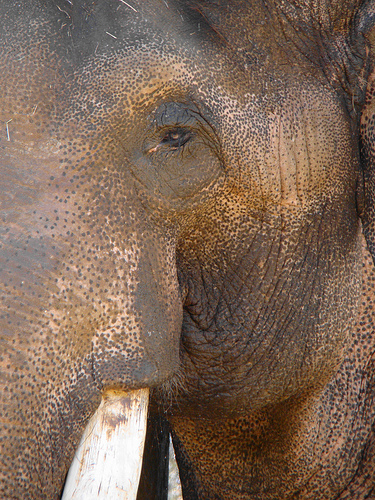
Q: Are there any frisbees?
A: No, there are no frisbees.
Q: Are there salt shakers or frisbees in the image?
A: No, there are no frisbees or salt shakers.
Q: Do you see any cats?
A: No, there are no cats.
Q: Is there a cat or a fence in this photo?
A: No, there are no cats or fences.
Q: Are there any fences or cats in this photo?
A: No, there are no cats or fences.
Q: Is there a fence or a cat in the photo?
A: No, there are no cats or fences.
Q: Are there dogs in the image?
A: No, there are no dogs.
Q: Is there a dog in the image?
A: No, there are no dogs.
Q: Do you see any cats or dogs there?
A: No, there are no dogs or cats.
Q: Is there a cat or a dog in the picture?
A: No, there are no dogs or cats.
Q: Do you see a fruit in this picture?
A: No, there are no fruits.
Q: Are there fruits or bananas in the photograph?
A: No, there are no fruits or bananas.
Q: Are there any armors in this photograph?
A: No, there are no armors.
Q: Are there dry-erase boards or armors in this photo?
A: No, there are no armors or dry-erase boards.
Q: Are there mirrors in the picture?
A: No, there are no mirrors.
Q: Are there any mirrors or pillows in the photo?
A: No, there are no mirrors or pillows.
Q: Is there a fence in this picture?
A: No, there are no fences.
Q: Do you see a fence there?
A: No, there are no fences.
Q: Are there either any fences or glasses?
A: No, there are no fences or glasses.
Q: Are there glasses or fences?
A: No, there are no fences or glasses.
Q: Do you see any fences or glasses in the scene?
A: No, there are no fences or glasses.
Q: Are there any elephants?
A: Yes, there is an elephant.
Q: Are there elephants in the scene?
A: Yes, there is an elephant.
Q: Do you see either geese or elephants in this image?
A: Yes, there is an elephant.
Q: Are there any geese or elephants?
A: Yes, there is an elephant.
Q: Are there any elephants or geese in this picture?
A: Yes, there is an elephant.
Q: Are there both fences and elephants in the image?
A: No, there is an elephant but no fences.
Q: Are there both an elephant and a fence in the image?
A: No, there is an elephant but no fences.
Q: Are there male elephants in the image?
A: Yes, there is a male elephant.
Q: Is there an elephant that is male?
A: Yes, there is an elephant that is male.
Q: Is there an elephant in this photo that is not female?
A: Yes, there is a male elephant.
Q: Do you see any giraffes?
A: No, there are no giraffes.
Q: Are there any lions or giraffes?
A: No, there are no giraffes or lions.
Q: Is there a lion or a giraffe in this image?
A: No, there are no giraffes or lions.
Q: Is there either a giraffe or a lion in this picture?
A: No, there are no giraffes or lions.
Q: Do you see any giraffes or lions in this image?
A: No, there are no giraffes or lions.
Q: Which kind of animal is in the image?
A: The animal is an elephant.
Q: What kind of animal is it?
A: The animal is an elephant.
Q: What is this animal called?
A: That is an elephant.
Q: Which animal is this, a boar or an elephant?
A: That is an elephant.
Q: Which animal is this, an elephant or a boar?
A: That is an elephant.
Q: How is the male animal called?
A: The animal is an elephant.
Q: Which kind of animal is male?
A: The animal is an elephant.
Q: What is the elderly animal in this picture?
A: The animal is an elephant.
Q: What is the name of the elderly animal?
A: The animal is an elephant.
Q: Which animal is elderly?
A: The animal is an elephant.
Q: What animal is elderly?
A: The animal is an elephant.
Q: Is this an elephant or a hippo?
A: This is an elephant.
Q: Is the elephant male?
A: Yes, the elephant is male.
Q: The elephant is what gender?
A: The elephant is male.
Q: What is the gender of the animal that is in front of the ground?
A: The elephant is male.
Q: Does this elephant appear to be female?
A: No, the elephant is male.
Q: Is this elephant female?
A: No, the elephant is male.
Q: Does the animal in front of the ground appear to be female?
A: No, the elephant is male.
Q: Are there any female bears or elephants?
A: No, there is an elephant but he is male.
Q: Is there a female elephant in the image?
A: No, there is an elephant but he is male.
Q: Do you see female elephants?
A: No, there is an elephant but he is male.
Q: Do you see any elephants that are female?
A: No, there is an elephant but he is male.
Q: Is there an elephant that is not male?
A: No, there is an elephant but he is male.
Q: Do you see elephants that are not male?
A: No, there is an elephant but he is male.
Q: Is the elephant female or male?
A: The elephant is male.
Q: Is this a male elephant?
A: Yes, this is a male elephant.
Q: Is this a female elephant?
A: No, this is a male elephant.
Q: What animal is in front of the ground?
A: The elephant is in front of the ground.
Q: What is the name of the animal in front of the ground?
A: The animal is an elephant.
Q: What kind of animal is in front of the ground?
A: The animal is an elephant.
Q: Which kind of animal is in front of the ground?
A: The animal is an elephant.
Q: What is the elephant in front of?
A: The elephant is in front of the ground.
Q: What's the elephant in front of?
A: The elephant is in front of the ground.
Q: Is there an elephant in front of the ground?
A: Yes, there is an elephant in front of the ground.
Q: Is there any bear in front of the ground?
A: No, there is an elephant in front of the ground.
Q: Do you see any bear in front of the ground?
A: No, there is an elephant in front of the ground.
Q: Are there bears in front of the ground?
A: No, there is an elephant in front of the ground.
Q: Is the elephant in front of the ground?
A: Yes, the elephant is in front of the ground.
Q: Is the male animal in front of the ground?
A: Yes, the elephant is in front of the ground.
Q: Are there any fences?
A: No, there are no fences.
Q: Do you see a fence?
A: No, there are no fences.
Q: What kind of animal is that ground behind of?
A: The ground is behind the elephant.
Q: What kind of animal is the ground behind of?
A: The ground is behind the elephant.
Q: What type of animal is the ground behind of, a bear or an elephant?
A: The ground is behind an elephant.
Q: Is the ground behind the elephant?
A: Yes, the ground is behind the elephant.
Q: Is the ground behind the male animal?
A: Yes, the ground is behind the elephant.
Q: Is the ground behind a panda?
A: No, the ground is behind the elephant.